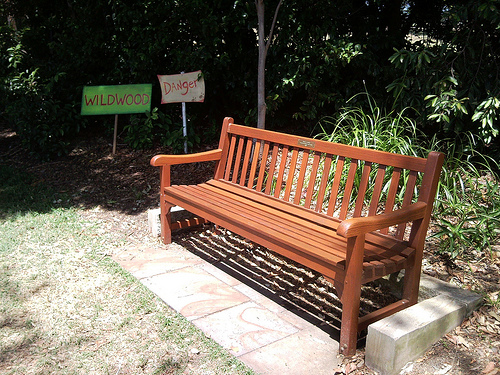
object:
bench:
[149, 115, 443, 357]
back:
[217, 115, 442, 212]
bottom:
[165, 175, 420, 279]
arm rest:
[334, 204, 430, 239]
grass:
[0, 204, 146, 374]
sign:
[78, 83, 153, 117]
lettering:
[85, 93, 150, 107]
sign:
[154, 69, 207, 103]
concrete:
[111, 247, 477, 374]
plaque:
[295, 138, 318, 149]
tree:
[1, 2, 121, 149]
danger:
[164, 80, 200, 96]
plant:
[310, 82, 491, 209]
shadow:
[440, 337, 494, 375]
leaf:
[336, 364, 367, 372]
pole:
[110, 115, 119, 157]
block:
[186, 297, 301, 361]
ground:
[8, 211, 497, 374]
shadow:
[0, 115, 227, 223]